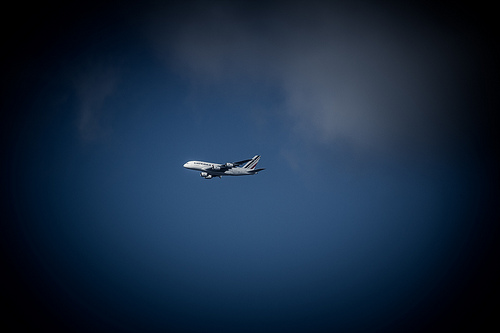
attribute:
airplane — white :
[175, 152, 268, 181]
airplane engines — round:
[196, 155, 239, 193]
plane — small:
[180, 152, 262, 178]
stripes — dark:
[242, 156, 260, 171]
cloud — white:
[156, 15, 448, 182]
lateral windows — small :
[191, 160, 213, 164]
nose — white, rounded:
[177, 156, 197, 174]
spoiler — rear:
[240, 151, 261, 170]